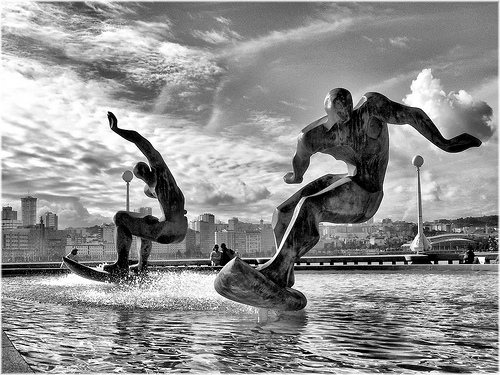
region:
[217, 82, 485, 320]
artistic stone surfer sculpture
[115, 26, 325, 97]
high thin white clouds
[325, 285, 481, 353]
small ripples in water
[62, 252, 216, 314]
water droplets from splashing surfers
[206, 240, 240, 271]
couple admiring water art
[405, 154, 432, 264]
tall thin background structure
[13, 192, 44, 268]
tall square high rise building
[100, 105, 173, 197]
sculpture left arm in air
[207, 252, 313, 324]
long stone surfboard sculpture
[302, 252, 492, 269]
long narrow water bridge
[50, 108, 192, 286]
statue of a surfer in the water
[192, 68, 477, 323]
statue of a surfer in the water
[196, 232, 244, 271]
couple near the water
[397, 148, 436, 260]
statue in the background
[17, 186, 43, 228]
building in the background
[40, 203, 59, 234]
building in the background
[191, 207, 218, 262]
building in the background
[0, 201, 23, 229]
building in the background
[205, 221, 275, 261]
building in the background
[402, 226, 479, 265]
building in the background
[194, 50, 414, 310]
metallic surfer surfing on a body of water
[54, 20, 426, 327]
two metallic surfers surfing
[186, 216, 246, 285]
couple on a small bridge behind metallic surfers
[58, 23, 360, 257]
strong overcast of clouds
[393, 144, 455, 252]
large cylimder structure with ball on top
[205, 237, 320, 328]
metallic surferboard on body of water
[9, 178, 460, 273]
city outline behind body of water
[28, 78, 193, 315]
metallic surfer with hand in air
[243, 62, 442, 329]
liquid metallic structure shaped like a surfer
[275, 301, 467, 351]
ripples in water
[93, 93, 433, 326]
two figures on surfboards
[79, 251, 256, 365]
water is being splashed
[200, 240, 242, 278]
two people near pool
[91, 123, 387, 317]
two figures in pool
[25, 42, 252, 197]
sky has striated clouds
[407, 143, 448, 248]
circular poles behind figures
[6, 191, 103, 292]
building left of pole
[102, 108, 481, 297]
figures' left arms are outstretched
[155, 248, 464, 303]
railing along edge of pond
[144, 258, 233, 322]
beads of water falling from figures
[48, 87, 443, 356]
Statues in the water.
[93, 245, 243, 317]
Water spray from the statues.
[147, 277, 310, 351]
Waves on the water.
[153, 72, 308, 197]
Clouds in the sky.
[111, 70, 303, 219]
Sky with clouds in it.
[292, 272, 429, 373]
Reflection in the water.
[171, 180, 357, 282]
Buildings in the background.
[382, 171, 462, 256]
Bridge in the background.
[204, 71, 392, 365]
Statue on a surfboard.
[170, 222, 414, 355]
Surfboard with the statue.